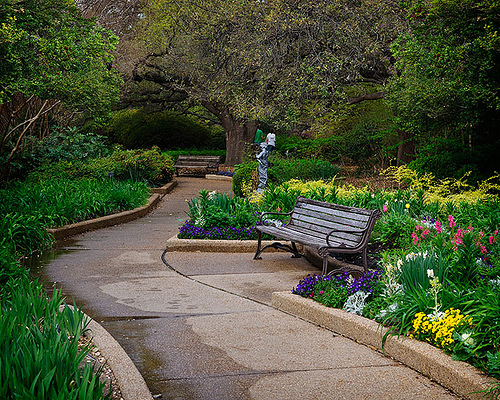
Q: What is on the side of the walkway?
A: Trees.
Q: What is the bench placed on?
A: A sidewalk.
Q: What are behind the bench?
A: Flowers.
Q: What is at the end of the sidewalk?
A: A bench.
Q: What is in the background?
A: Trees.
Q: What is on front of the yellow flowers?
A: A small grey bench.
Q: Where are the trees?
A: All around.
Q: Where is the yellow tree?
A: In a distance.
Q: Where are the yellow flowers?
A: On the side of the path.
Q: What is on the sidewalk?
A: Water.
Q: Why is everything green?
A: It is blooming.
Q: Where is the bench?
A: Next to the sidewalk.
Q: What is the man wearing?
A: A green shirt.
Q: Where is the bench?
A: On the sidewalk.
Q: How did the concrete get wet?
A: It rained.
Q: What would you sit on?
A: The bench.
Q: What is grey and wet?
A: The walkway.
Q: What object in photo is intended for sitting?
A: Bench.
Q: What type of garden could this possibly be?
A: Botanical garden.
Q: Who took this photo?
A: Photographer.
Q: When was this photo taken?
A: Daytime.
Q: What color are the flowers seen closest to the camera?
A: Yellow.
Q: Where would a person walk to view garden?
A: Walking path.